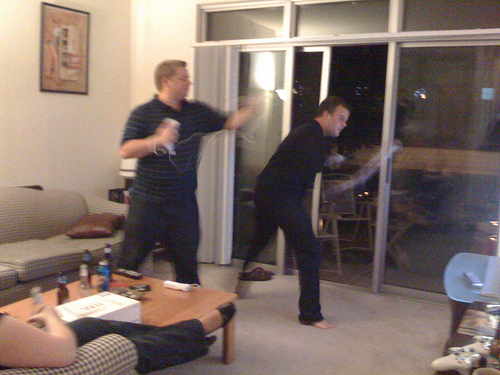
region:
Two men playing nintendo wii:
[108, 53, 410, 333]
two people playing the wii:
[114, 56, 375, 336]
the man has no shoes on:
[284, 308, 341, 333]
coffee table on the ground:
[1, 261, 244, 360]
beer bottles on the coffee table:
[40, 243, 117, 317]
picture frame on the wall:
[34, 0, 99, 105]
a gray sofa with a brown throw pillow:
[0, 178, 165, 297]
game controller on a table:
[428, 337, 488, 368]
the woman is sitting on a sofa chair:
[1, 243, 236, 373]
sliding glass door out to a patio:
[197, 36, 487, 297]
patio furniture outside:
[303, 161, 418, 303]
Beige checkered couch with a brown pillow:
[1, 185, 154, 303]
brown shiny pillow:
[65, 212, 125, 239]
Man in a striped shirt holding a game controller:
[118, 58, 260, 273]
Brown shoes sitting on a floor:
[236, 265, 276, 283]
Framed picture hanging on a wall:
[39, 0, 91, 95]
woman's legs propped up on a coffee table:
[1, 294, 241, 373]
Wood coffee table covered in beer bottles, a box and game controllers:
[3, 267, 239, 362]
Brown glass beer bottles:
[78, 240, 110, 293]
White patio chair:
[323, 168, 374, 253]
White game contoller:
[427, 333, 497, 373]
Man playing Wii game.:
[116, 53, 263, 290]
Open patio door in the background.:
[287, 41, 388, 279]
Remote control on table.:
[457, 266, 483, 291]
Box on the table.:
[53, 285, 149, 328]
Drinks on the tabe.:
[75, 243, 119, 293]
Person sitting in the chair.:
[0, 283, 237, 373]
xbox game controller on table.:
[429, 335, 488, 373]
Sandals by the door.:
[234, 263, 281, 288]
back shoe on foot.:
[195, 297, 241, 334]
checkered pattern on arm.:
[0, 328, 149, 374]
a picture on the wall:
[43, 3, 94, 95]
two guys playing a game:
[113, 53, 362, 341]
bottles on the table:
[72, 245, 119, 277]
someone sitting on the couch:
[11, 298, 188, 373]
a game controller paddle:
[436, 335, 488, 369]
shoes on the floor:
[235, 260, 273, 287]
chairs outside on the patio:
[314, 155, 375, 277]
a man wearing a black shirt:
[247, 98, 373, 344]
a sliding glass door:
[206, 33, 498, 283]